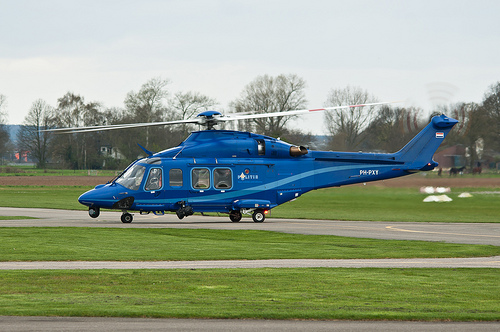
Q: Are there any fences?
A: No, there are no fences.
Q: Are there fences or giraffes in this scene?
A: No, there are no fences or giraffes.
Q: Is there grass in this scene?
A: Yes, there is grass.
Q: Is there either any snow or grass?
A: Yes, there is grass.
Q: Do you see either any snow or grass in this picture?
A: Yes, there is grass.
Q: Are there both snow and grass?
A: No, there is grass but no snow.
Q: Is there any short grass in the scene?
A: Yes, there is short grass.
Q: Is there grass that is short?
A: Yes, there is grass that is short.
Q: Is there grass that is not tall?
A: Yes, there is short grass.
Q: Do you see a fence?
A: No, there are no fences.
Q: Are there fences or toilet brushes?
A: No, there are no fences or toilet brushes.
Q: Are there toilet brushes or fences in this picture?
A: No, there are no fences or toilet brushes.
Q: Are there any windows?
A: Yes, there is a window.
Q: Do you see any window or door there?
A: Yes, there is a window.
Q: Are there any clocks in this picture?
A: No, there are no clocks.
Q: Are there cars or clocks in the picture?
A: No, there are no clocks or cars.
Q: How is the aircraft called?
A: The aircraft is a helicopter.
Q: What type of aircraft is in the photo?
A: The aircraft is a helicopter.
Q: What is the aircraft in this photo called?
A: The aircraft is a helicopter.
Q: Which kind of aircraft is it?
A: The aircraft is a helicopter.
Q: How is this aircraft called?
A: That is a helicopter.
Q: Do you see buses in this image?
A: No, there are no buses.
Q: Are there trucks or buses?
A: No, there are no buses or trucks.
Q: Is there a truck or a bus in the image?
A: No, there are no buses or trucks.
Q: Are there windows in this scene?
A: Yes, there is a window.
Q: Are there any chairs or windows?
A: Yes, there is a window.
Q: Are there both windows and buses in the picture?
A: No, there is a window but no buses.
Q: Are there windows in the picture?
A: Yes, there is a window.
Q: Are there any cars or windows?
A: Yes, there is a window.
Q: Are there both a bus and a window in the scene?
A: No, there is a window but no buses.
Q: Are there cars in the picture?
A: No, there are no cars.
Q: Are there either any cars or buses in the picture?
A: No, there are no cars or buses.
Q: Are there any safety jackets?
A: No, there are no safety jackets.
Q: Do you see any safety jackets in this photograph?
A: No, there are no safety jackets.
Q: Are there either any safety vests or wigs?
A: No, there are no safety vests or wigs.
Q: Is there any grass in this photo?
A: Yes, there is grass.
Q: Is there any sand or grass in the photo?
A: Yes, there is grass.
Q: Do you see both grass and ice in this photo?
A: No, there is grass but no ice.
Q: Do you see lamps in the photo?
A: No, there are no lamps.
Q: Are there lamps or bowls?
A: No, there are no lamps or bowls.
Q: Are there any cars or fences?
A: No, there are no cars or fences.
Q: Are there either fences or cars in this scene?
A: No, there are no cars or fences.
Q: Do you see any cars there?
A: No, there are no cars.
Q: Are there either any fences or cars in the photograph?
A: No, there are no cars or fences.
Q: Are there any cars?
A: No, there are no cars.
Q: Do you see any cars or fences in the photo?
A: No, there are no cars or fences.